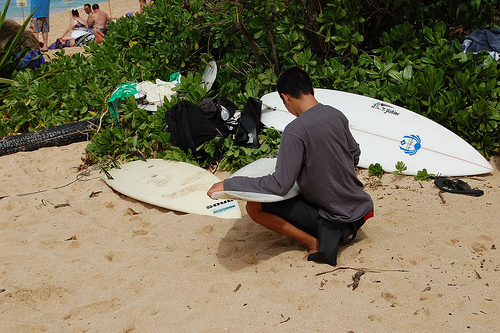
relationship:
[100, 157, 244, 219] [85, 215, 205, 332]
surfboard in sand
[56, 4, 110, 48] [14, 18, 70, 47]
people on beach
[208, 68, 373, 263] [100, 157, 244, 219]
man near surfboard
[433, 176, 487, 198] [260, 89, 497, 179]
strap for surfboard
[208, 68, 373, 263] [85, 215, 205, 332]
man in sand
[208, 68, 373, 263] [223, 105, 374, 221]
man in shirt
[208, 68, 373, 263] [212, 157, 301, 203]
man holding board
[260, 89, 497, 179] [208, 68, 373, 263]
surfboard near man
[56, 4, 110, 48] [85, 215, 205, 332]
people in sand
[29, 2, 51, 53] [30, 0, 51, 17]
man in shirt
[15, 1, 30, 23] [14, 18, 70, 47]
sign on beach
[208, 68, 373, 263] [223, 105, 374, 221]
man wearing shirt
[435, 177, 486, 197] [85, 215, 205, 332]
slipper on sand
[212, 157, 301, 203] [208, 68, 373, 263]
board in front of man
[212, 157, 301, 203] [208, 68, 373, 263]
board right of man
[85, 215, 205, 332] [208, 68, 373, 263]
sand beneath man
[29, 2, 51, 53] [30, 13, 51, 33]
man has shorts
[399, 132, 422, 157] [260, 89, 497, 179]
sticker on surfboard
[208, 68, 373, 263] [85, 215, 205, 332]
man squatting on sand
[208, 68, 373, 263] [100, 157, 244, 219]
man holding surfboard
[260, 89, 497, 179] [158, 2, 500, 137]
surfboard against bushes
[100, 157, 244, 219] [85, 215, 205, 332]
surfboard on sand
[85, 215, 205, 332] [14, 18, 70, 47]
sand on beach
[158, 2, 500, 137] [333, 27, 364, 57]
bushes with leaves